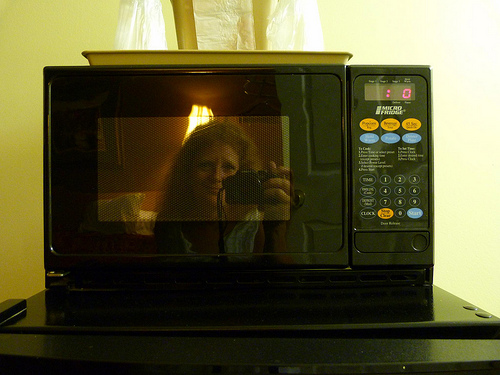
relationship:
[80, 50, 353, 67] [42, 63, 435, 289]
pan on microwave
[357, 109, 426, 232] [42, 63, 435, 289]
control panel of microwave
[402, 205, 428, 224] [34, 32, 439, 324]
button on microwave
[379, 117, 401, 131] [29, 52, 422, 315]
button on microwave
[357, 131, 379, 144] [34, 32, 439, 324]
button on microwave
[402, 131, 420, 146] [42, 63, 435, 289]
button on microwave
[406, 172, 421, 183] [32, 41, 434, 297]
button on microwave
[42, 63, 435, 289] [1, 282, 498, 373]
microwave on table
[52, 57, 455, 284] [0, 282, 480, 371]
microwave on fridge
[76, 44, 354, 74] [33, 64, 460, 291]
pan on a microwave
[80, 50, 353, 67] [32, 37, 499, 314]
pan on a microwave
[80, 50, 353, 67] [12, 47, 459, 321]
pan on a microwave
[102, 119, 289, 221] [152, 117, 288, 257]
image of a woman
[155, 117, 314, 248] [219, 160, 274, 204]
woman holding camera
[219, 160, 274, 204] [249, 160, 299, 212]
camera in hand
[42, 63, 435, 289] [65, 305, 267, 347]
microwave on table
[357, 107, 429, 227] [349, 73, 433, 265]
button appearing on panel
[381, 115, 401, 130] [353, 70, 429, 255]
button on control panel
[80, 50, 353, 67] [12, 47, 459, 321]
pan kept on microwave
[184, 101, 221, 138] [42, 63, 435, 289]
light lit inside microwave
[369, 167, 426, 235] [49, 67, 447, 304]
button on microwave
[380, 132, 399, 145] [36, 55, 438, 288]
button on microwave